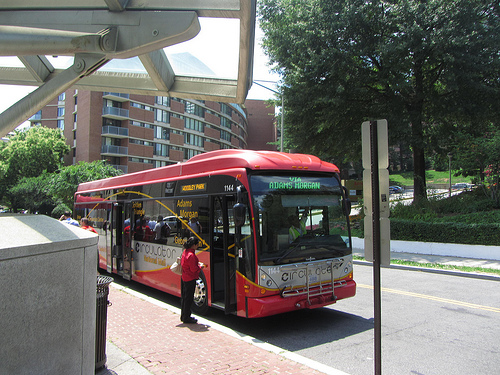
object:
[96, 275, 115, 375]
trash bin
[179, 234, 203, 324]
person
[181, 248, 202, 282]
shirt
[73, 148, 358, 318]
bus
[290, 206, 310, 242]
driver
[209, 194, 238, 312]
door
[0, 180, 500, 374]
street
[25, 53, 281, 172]
building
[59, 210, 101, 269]
people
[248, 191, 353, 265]
windshield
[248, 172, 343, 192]
display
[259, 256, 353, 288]
rack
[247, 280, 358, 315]
bumper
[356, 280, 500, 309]
line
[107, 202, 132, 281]
rear door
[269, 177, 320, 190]
word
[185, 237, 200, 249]
hair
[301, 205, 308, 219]
hand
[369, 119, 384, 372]
pole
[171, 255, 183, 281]
purse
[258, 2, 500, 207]
tree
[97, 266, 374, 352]
shadow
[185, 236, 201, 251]
head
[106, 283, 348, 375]
side